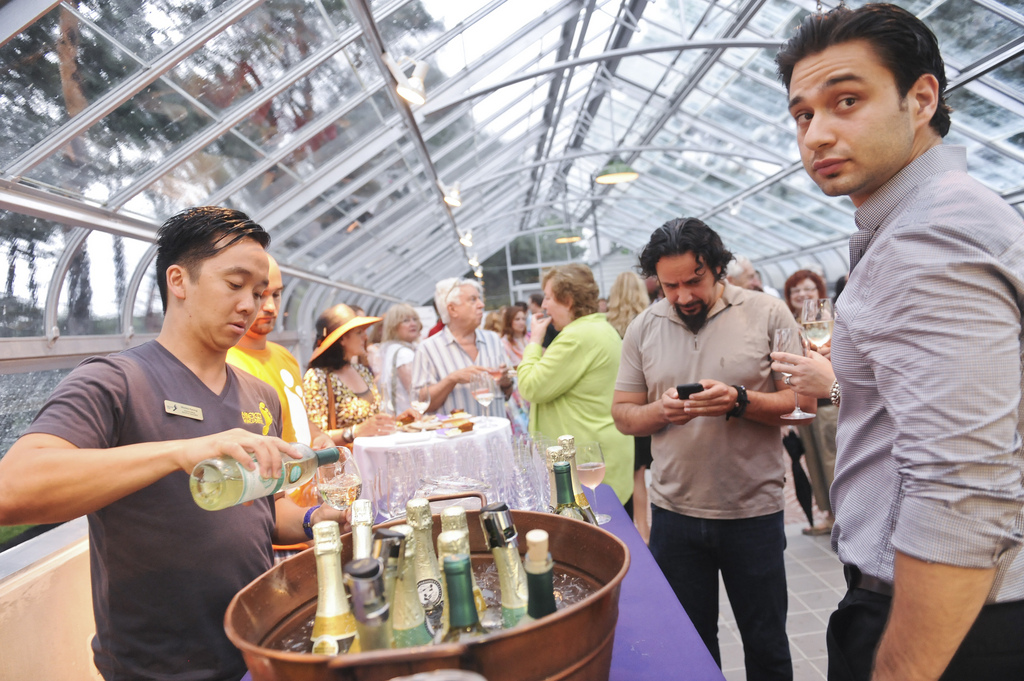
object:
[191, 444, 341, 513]
bottle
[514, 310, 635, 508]
jacket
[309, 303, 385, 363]
hat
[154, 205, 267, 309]
hair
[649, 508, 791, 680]
pants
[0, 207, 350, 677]
man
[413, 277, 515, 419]
man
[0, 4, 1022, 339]
ceiling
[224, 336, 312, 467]
shirt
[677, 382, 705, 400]
phone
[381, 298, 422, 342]
hair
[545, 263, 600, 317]
hair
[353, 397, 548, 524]
table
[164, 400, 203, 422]
tag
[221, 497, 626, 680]
bucket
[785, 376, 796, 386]
ring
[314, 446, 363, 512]
glass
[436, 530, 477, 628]
bottle